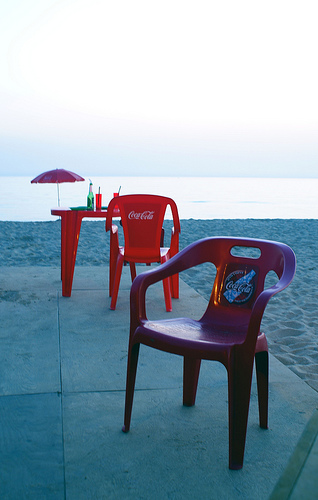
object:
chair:
[121, 233, 297, 468]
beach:
[0, 253, 313, 498]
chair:
[105, 192, 181, 313]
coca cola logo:
[220, 259, 257, 309]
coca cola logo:
[128, 206, 159, 222]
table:
[48, 208, 139, 298]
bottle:
[86, 185, 97, 208]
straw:
[89, 177, 95, 183]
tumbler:
[96, 193, 102, 210]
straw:
[96, 186, 102, 192]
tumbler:
[113, 192, 120, 210]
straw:
[117, 182, 127, 193]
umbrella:
[30, 166, 86, 186]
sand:
[0, 218, 40, 263]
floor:
[7, 387, 124, 497]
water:
[1, 176, 303, 225]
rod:
[56, 180, 64, 215]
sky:
[3, 4, 315, 182]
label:
[88, 196, 96, 212]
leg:
[63, 218, 75, 302]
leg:
[109, 261, 125, 310]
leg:
[124, 340, 136, 435]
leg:
[225, 365, 250, 474]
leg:
[180, 358, 202, 410]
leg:
[255, 361, 270, 432]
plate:
[70, 205, 91, 211]